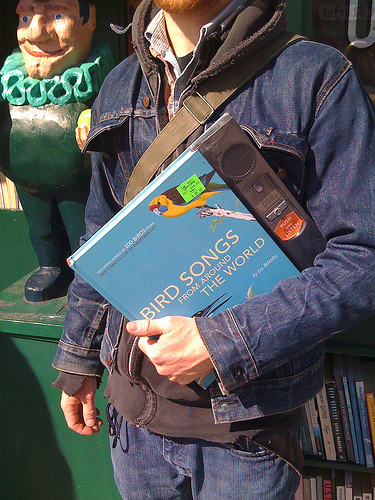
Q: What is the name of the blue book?
A: Bird songs from around the world.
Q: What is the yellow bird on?
A: Blue book.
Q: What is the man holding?
A: A bird.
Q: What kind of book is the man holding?
A: A book that makes sounds.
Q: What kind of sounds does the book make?
A: Bird songs.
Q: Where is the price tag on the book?
A: On the cover.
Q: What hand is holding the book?
A: The left hand.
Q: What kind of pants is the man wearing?
A: Blue jeans.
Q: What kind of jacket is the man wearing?
A: A blue jean jacket.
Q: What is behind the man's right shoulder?
A: A statue of a man.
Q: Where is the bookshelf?
A: Behind the man.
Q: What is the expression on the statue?
A: Smiling.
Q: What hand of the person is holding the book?
A: Their left hand.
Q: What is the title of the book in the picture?
A: Bird Songs From Around The World.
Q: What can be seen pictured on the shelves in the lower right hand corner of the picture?
A: Books.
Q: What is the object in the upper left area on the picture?
A: A statue.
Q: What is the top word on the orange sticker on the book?
A: Push.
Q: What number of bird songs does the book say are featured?
A: 200.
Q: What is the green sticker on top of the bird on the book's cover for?
A: A price tag.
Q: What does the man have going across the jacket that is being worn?
A: A strap.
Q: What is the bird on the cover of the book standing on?
A: A branch.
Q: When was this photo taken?
A: Day time.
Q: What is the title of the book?
A: Bird Songs from Around the World.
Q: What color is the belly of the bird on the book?
A: Yellow.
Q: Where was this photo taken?
A: Book store.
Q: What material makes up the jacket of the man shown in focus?
A: Jean.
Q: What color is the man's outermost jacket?
A: Blue.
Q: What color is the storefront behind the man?
A: Green.